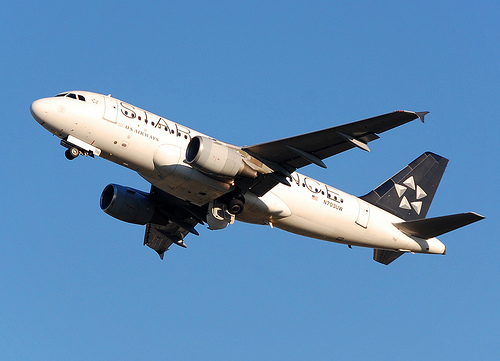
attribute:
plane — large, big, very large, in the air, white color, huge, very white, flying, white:
[30, 89, 487, 266]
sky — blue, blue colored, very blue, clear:
[4, 2, 499, 360]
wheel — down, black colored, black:
[228, 200, 243, 215]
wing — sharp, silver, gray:
[246, 111, 427, 164]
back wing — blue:
[404, 212, 486, 241]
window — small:
[125, 112, 130, 118]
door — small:
[110, 100, 120, 117]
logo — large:
[122, 101, 197, 140]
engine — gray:
[187, 136, 252, 183]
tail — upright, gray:
[368, 152, 449, 221]